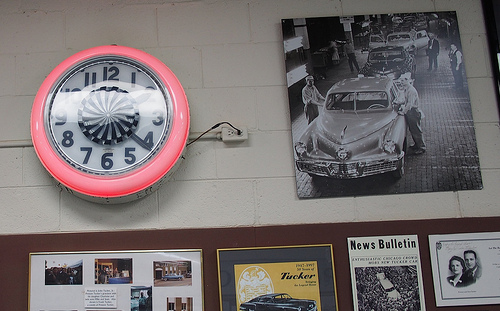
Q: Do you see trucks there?
A: No, there are no trucks.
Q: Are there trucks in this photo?
A: No, there are no trucks.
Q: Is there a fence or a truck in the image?
A: No, there are no trucks or fences.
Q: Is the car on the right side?
A: Yes, the car is on the right of the image.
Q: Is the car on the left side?
A: No, the car is on the right of the image.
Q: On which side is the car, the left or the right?
A: The car is on the right of the image.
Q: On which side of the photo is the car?
A: The car is on the right of the image.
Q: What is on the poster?
A: The car is on the poster.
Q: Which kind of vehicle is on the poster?
A: The vehicle is a car.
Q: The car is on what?
A: The car is on the poster.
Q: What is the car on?
A: The car is on the poster.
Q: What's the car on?
A: The car is on the poster.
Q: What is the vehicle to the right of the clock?
A: The vehicle is a car.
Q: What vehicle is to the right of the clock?
A: The vehicle is a car.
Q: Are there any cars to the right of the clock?
A: Yes, there is a car to the right of the clock.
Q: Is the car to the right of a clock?
A: Yes, the car is to the right of a clock.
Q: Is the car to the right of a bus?
A: No, the car is to the right of a clock.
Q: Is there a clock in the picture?
A: Yes, there is a clock.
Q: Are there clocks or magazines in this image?
A: Yes, there is a clock.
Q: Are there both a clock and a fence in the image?
A: No, there is a clock but no fences.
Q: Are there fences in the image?
A: No, there are no fences.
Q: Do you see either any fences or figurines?
A: No, there are no fences or figurines.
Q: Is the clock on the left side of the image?
A: Yes, the clock is on the left of the image.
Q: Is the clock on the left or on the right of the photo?
A: The clock is on the left of the image.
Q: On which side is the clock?
A: The clock is on the left of the image.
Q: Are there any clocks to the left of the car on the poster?
A: Yes, there is a clock to the left of the car.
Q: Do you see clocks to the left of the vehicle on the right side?
A: Yes, there is a clock to the left of the car.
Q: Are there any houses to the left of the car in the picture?
A: No, there is a clock to the left of the car.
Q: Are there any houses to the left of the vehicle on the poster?
A: No, there is a clock to the left of the car.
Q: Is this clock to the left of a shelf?
A: No, the clock is to the left of the car.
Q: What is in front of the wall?
A: The clock is in front of the wall.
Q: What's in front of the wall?
A: The clock is in front of the wall.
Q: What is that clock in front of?
A: The clock is in front of the wall.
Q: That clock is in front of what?
A: The clock is in front of the wall.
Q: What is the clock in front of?
A: The clock is in front of the wall.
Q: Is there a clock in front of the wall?
A: Yes, there is a clock in front of the wall.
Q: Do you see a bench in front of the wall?
A: No, there is a clock in front of the wall.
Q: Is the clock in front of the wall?
A: Yes, the clock is in front of the wall.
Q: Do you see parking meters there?
A: No, there are no parking meters.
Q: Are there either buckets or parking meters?
A: No, there are no parking meters or buckets.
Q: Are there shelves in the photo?
A: No, there are no shelves.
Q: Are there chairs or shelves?
A: No, there are no shelves or chairs.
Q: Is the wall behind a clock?
A: Yes, the wall is behind a clock.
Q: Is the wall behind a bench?
A: No, the wall is behind a clock.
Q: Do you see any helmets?
A: No, there are no helmets.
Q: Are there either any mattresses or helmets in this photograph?
A: No, there are no helmets or mattresses.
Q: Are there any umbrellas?
A: No, there are no umbrellas.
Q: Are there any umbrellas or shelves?
A: No, there are no umbrellas or shelves.